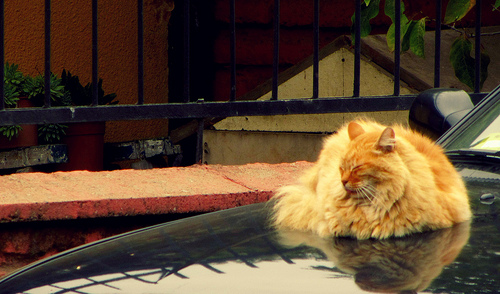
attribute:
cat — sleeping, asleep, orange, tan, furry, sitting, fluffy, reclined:
[275, 117, 474, 240]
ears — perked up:
[346, 117, 400, 154]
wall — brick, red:
[0, 210, 183, 270]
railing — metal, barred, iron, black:
[1, 1, 499, 119]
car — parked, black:
[15, 82, 500, 291]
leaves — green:
[6, 66, 40, 95]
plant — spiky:
[53, 66, 111, 106]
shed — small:
[178, 27, 493, 161]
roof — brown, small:
[332, 25, 498, 90]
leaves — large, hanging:
[350, 1, 486, 94]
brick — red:
[34, 221, 106, 254]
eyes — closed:
[336, 162, 368, 172]